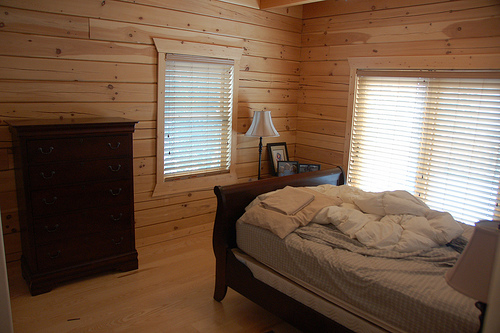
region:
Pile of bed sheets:
[249, 180, 468, 267]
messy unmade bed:
[209, 163, 498, 331]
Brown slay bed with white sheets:
[209, 165, 487, 332]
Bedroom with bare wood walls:
[0, 0, 495, 330]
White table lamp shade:
[241, 108, 279, 140]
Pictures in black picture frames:
[265, 140, 319, 175]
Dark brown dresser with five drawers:
[6, 113, 138, 295]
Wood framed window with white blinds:
[345, 59, 499, 228]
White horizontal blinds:
[148, 35, 238, 191]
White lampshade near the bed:
[445, 218, 498, 303]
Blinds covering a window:
[161, 48, 236, 180]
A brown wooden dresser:
[9, 111, 142, 294]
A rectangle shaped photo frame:
[266, 136, 290, 176]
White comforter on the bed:
[323, 182, 462, 254]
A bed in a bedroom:
[208, 164, 489, 329]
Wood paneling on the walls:
[1, 1, 499, 241]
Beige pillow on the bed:
[236, 182, 339, 241]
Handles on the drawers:
[101, 133, 131, 254]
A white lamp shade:
[244, 104, 279, 184]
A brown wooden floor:
[7, 232, 300, 331]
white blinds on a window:
[163, 53, 236, 178]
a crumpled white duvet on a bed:
[303, 183, 467, 255]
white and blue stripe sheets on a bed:
[234, 223, 486, 331]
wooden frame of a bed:
[208, 165, 351, 330]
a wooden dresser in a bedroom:
[5, 115, 137, 297]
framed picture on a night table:
[276, 158, 321, 175]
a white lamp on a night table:
[246, 108, 279, 181]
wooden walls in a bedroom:
[2, 3, 499, 286]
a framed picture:
[266, 141, 290, 177]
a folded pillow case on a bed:
[263, 184, 314, 217]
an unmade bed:
[211, 166, 497, 331]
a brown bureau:
[2, 115, 137, 292]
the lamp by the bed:
[441, 217, 496, 327]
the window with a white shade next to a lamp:
[150, 35, 242, 195]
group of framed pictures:
[265, 140, 320, 175]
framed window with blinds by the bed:
[340, 50, 495, 220]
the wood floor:
[5, 230, 295, 330]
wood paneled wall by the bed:
[295, 0, 495, 225]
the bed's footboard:
[210, 162, 345, 298]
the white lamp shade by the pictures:
[241, 110, 278, 138]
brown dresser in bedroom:
[1, 108, 147, 294]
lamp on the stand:
[245, 106, 280, 180]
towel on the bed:
[257, 190, 316, 214]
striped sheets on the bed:
[310, 245, 337, 271]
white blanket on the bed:
[340, 202, 390, 231]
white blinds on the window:
[346, 75, 459, 148]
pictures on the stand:
[267, 139, 321, 174]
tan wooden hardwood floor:
[123, 285, 170, 322]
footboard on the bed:
[210, 185, 241, 223]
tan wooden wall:
[257, 46, 316, 56]